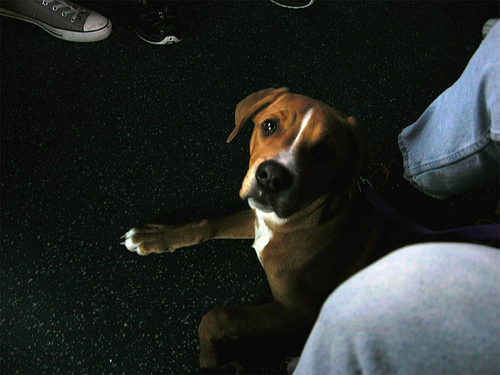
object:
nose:
[254, 158, 295, 194]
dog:
[118, 83, 499, 374]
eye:
[259, 116, 279, 138]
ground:
[0, 0, 499, 374]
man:
[287, 16, 498, 373]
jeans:
[289, 19, 497, 374]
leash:
[357, 176, 499, 244]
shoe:
[0, 0, 114, 43]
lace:
[39, 0, 90, 23]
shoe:
[129, 0, 189, 47]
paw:
[118, 220, 172, 256]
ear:
[226, 85, 289, 143]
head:
[225, 85, 370, 224]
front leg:
[196, 298, 306, 374]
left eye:
[312, 139, 338, 164]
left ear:
[329, 111, 369, 203]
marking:
[285, 103, 317, 155]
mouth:
[242, 190, 277, 217]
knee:
[290, 240, 498, 373]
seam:
[406, 130, 498, 176]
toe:
[120, 239, 132, 248]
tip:
[82, 7, 113, 45]